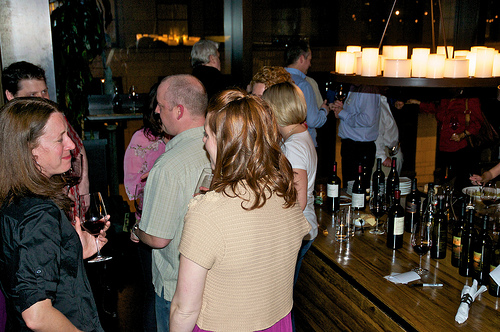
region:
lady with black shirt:
[5, 95, 110, 325]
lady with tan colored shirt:
[165, 90, 330, 325]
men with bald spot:
[130, 70, 206, 150]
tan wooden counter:
[325, 245, 421, 325]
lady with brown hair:
[1, 85, 101, 325]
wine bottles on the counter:
[322, 166, 497, 262]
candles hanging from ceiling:
[323, 5, 493, 98]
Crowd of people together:
[3, 35, 323, 328]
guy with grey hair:
[130, 61, 210, 256]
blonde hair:
[266, 80, 321, 128]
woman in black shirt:
[0, 91, 110, 330]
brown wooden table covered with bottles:
[264, 141, 498, 330]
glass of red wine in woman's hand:
[72, 186, 123, 271]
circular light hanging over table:
[323, 0, 498, 110]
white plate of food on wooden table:
[455, 178, 498, 205]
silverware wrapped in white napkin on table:
[451, 270, 489, 330]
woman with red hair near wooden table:
[146, 84, 320, 330]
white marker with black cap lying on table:
[410, 278, 449, 290]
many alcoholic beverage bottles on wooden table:
[321, 151, 498, 296]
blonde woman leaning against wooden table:
[246, 71, 328, 329]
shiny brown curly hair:
[198, 91, 297, 219]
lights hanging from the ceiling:
[296, 33, 496, 105]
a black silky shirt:
[1, 180, 148, 322]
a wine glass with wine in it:
[53, 184, 120, 307]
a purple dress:
[192, 283, 289, 330]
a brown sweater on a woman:
[167, 168, 335, 328]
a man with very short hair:
[123, 67, 212, 124]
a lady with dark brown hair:
[3, 104, 112, 206]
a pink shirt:
[112, 120, 179, 211]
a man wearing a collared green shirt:
[124, 116, 236, 293]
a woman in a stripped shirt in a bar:
[163, 88, 304, 330]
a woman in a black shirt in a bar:
[2, 93, 99, 330]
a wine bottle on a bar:
[383, 184, 405, 250]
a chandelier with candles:
[328, 33, 498, 88]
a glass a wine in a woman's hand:
[75, 187, 112, 267]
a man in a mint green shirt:
[138, 73, 209, 318]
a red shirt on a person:
[422, 95, 479, 149]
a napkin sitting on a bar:
[385, 269, 423, 289]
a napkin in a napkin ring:
[454, 279, 487, 324]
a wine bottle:
[431, 193, 447, 266]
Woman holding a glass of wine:
[5, 108, 126, 280]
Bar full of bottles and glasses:
[315, 142, 499, 282]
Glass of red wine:
[69, 185, 121, 278]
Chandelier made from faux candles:
[315, 5, 497, 103]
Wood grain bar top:
[328, 257, 431, 328]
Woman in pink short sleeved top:
[158, 95, 305, 329]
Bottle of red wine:
[380, 181, 411, 258]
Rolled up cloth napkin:
[440, 272, 484, 324]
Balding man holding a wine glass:
[121, 65, 210, 255]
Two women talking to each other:
[1, 74, 285, 276]